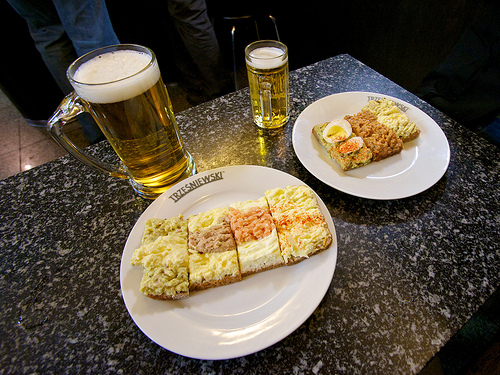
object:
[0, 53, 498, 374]
counter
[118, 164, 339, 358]
plate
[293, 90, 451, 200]
plate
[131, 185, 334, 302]
food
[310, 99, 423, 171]
food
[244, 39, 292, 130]
mug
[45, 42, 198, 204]
mug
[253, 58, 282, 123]
beer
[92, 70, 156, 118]
beer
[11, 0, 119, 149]
jeans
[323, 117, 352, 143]
egg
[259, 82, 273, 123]
handle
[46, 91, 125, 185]
handle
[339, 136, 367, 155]
paprika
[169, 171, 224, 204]
writing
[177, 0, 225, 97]
leg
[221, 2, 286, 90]
chair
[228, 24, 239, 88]
leg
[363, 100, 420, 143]
cake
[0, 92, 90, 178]
floor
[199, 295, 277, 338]
part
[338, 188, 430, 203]
edge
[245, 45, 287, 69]
foam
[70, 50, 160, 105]
foam